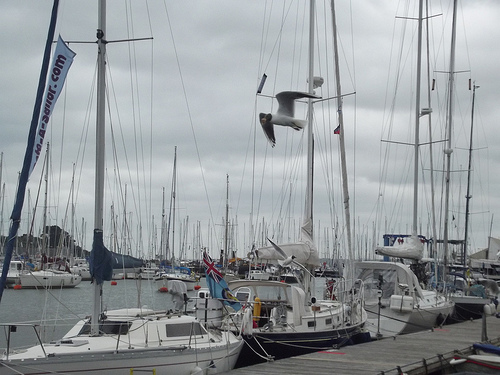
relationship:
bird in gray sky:
[240, 76, 329, 142] [0, 0, 500, 260]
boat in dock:
[1, 2, 243, 373] [215, 315, 500, 374]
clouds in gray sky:
[0, 0, 500, 261] [0, 0, 500, 260]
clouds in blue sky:
[0, 0, 500, 261] [208, 67, 254, 97]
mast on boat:
[90, 0, 106, 338] [1, 2, 243, 373]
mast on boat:
[299, 0, 315, 291] [229, 275, 366, 341]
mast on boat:
[403, 5, 438, 263] [382, 262, 474, 309]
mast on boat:
[90, 0, 106, 338] [146, 267, 180, 282]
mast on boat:
[167, 145, 180, 272] [146, 267, 180, 282]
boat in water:
[1, 2, 243, 373] [1, 265, 357, 357]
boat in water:
[1, 2, 243, 373] [6, 254, 384, 375]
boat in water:
[1, 2, 243, 373] [5, 291, 94, 314]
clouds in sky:
[0, 0, 500, 261] [7, 17, 470, 251]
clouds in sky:
[134, 92, 259, 172] [7, 17, 470, 251]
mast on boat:
[90, 0, 106, 338] [0, 298, 242, 371]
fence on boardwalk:
[389, 338, 497, 373] [230, 317, 492, 373]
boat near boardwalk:
[188, 285, 365, 352] [230, 317, 492, 373]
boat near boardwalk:
[193, 0, 366, 351] [230, 317, 492, 373]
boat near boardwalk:
[1, 2, 243, 373] [230, 317, 492, 373]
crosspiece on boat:
[53, 35, 156, 45] [2, 263, 82, 288]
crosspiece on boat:
[395, 9, 445, 23] [2, 263, 82, 288]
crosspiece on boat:
[379, 137, 449, 148] [2, 263, 82, 288]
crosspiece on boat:
[452, 145, 489, 151] [2, 263, 82, 288]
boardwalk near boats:
[218, 314, 498, 373] [179, 259, 401, 310]